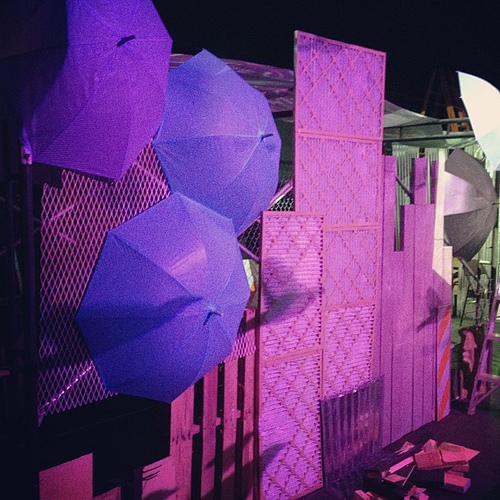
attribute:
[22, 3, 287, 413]
umbrellas — three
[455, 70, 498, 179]
umbrella —  white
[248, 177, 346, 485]
pallet —  purple,  wooden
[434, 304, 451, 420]
construction sign —  orange and purple, for contruction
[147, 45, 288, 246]
umbrella —  purple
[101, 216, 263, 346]
umbrella —  purple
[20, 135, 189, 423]
grate —  metal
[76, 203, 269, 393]
umbrella —   Purple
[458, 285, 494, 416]
ladder —  purple,  step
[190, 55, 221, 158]
umbrella —  purple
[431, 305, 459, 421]
stripes —  orange and gray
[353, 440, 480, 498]
pile — blocks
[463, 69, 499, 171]
grey umbrella —  grey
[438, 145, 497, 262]
umbrella — gray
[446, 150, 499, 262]
umbrella — white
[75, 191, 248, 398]
umbrella — blue, open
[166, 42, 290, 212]
umbrella — blue, open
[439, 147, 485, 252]
one — black